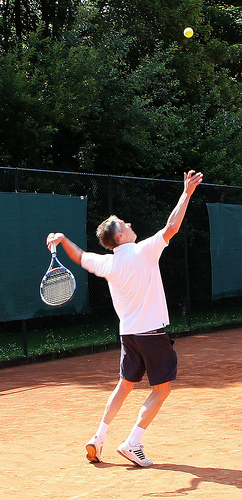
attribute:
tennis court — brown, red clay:
[0, 323, 241, 500]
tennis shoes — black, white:
[118, 442, 154, 468]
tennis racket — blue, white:
[40, 240, 76, 307]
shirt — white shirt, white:
[79, 232, 171, 335]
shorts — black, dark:
[118, 326, 179, 384]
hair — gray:
[95, 214, 120, 250]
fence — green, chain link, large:
[1, 164, 240, 367]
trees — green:
[0, 0, 241, 203]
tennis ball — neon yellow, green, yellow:
[184, 25, 196, 39]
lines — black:
[133, 448, 146, 462]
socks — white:
[127, 425, 146, 448]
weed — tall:
[179, 298, 191, 334]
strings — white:
[42, 270, 71, 304]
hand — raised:
[182, 165, 205, 195]